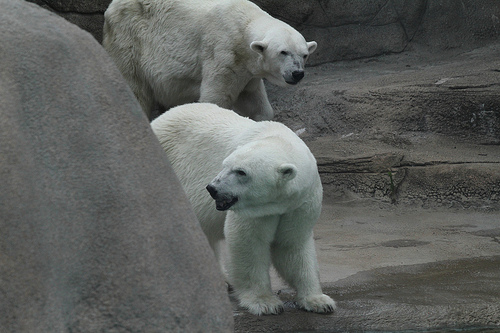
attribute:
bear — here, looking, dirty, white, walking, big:
[160, 109, 340, 315]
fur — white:
[143, 8, 201, 54]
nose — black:
[277, 61, 312, 89]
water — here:
[379, 309, 494, 331]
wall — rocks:
[328, 15, 483, 81]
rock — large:
[3, 26, 169, 332]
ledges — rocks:
[330, 78, 490, 188]